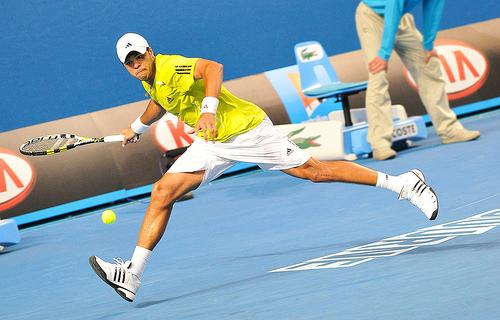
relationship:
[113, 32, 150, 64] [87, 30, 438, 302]
cap on man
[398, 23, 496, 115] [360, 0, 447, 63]
logo on blue shirt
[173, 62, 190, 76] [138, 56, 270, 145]
stripes on shirt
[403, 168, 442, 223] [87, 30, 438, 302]
shoe on man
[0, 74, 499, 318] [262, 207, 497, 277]
tennis court with letters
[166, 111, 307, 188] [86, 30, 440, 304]
shorts on a man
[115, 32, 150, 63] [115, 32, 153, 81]
cap on a mans head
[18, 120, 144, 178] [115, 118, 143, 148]
racket in hand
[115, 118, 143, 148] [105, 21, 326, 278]
hand of man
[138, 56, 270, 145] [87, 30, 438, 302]
shirt on man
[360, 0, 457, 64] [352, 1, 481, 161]
blue shirt on man